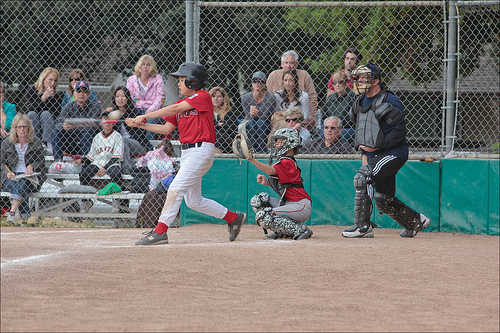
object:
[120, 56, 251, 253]
boy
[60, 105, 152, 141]
bat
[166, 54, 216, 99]
helmet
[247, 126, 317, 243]
boy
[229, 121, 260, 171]
glove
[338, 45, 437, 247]
man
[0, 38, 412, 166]
people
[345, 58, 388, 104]
faceguard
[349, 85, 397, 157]
vest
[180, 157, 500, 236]
barrier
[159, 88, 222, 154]
jersey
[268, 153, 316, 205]
jersey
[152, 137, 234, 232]
pants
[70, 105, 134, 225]
boy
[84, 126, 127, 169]
jersey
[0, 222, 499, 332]
ground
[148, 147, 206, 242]
leg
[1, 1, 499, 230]
fence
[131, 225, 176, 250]
shoe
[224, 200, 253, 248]
shoe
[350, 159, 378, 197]
kneepad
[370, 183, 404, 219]
kneepad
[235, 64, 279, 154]
woman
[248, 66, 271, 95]
cap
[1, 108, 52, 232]
woman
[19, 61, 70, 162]
woman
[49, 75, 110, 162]
man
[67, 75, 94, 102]
cap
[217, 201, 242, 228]
sock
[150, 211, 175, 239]
sock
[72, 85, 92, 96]
sunglasses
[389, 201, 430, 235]
shinguards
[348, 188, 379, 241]
shinguards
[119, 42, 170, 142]
woman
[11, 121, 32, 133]
glasses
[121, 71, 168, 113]
jacket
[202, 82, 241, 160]
woman